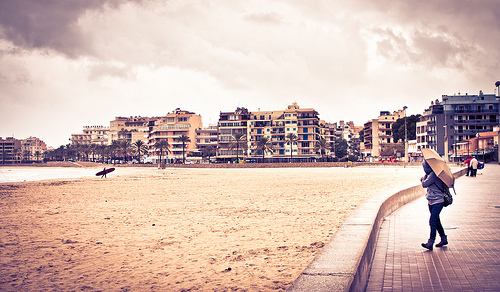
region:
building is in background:
[0, 135, 52, 167]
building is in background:
[66, 106, 203, 164]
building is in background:
[214, 102, 342, 162]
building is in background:
[358, 104, 405, 156]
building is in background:
[415, 92, 499, 159]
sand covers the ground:
[0, 162, 413, 289]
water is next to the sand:
[0, 160, 197, 187]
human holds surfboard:
[92, 164, 117, 179]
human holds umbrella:
[413, 146, 460, 252]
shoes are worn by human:
[420, 231, 450, 251]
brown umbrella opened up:
[420, 150, 457, 186]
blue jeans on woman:
[420, 201, 452, 251]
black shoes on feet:
[415, 237, 461, 252]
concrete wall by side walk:
[287, 193, 402, 290]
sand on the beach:
[63, 170, 267, 290]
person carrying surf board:
[90, 163, 117, 182]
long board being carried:
[90, 168, 120, 180]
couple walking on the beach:
[459, 146, 491, 180]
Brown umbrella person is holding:
[417, 141, 460, 189]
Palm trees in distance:
[131, 128, 342, 164]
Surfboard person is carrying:
[92, 165, 116, 177]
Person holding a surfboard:
[100, 165, 108, 179]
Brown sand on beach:
[0, 167, 421, 289]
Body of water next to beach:
[0, 163, 177, 187]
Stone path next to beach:
[367, 161, 498, 290]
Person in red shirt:
[461, 153, 473, 176]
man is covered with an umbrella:
[398, 129, 476, 269]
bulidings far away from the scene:
[176, 104, 358, 173]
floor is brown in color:
[75, 202, 199, 257]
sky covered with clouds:
[161, 34, 255, 80]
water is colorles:
[41, 164, 72, 175]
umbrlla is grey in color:
[423, 124, 451, 181]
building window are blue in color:
[258, 113, 307, 152]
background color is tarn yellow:
[99, 102, 328, 262]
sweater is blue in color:
[426, 173, 441, 199]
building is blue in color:
[445, 82, 490, 132]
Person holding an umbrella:
[418, 158, 452, 251]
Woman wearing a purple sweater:
[419, 158, 453, 250]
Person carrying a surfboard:
[100, 164, 110, 177]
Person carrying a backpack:
[415, 160, 447, 248]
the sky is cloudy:
[171, 30, 224, 53]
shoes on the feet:
[418, 241, 446, 251]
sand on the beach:
[224, 184, 277, 211]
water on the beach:
[31, 172, 48, 178]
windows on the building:
[235, 140, 253, 159]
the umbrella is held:
[422, 154, 457, 179]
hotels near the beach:
[134, 102, 334, 162]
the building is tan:
[187, 117, 201, 127]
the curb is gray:
[307, 255, 349, 275]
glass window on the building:
[255, 125, 261, 132]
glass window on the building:
[252, 132, 255, 138]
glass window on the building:
[292, 125, 295, 131]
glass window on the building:
[300, 123, 306, 133]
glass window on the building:
[301, 132, 304, 137]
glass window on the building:
[300, 140, 307, 146]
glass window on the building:
[300, 146, 310, 152]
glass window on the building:
[182, 112, 187, 119]